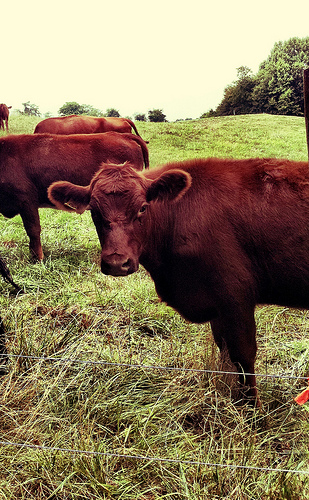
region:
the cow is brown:
[50, 169, 269, 375]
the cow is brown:
[4, 124, 177, 247]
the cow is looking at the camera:
[48, 139, 215, 332]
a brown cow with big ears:
[47, 152, 186, 296]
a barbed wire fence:
[82, 363, 282, 485]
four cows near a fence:
[1, 101, 258, 267]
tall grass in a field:
[24, 348, 173, 410]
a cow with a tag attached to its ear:
[50, 150, 183, 290]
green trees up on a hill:
[168, 43, 305, 132]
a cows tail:
[114, 133, 157, 170]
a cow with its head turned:
[69, 156, 188, 282]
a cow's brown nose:
[80, 239, 142, 293]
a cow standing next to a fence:
[37, 149, 281, 474]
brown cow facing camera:
[41, 153, 305, 425]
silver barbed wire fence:
[1, 337, 307, 498]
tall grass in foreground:
[4, 233, 305, 493]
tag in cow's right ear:
[63, 200, 80, 216]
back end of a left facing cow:
[95, 130, 161, 177]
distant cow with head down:
[25, 112, 143, 141]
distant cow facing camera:
[0, 100, 13, 132]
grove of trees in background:
[11, 32, 305, 118]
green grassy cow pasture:
[0, 100, 306, 498]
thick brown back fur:
[142, 151, 307, 179]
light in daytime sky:
[3, 0, 307, 115]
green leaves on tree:
[258, 38, 307, 112]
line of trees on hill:
[18, 36, 308, 159]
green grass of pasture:
[0, 117, 306, 327]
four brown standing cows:
[0, 102, 306, 382]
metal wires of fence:
[0, 352, 308, 475]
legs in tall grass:
[7, 325, 299, 493]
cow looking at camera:
[49, 161, 190, 275]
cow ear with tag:
[46, 181, 90, 214]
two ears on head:
[50, 161, 192, 277]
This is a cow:
[44, 156, 302, 411]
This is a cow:
[0, 128, 158, 297]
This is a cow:
[28, 103, 164, 165]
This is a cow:
[0, 94, 18, 128]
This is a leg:
[218, 291, 276, 453]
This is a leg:
[199, 301, 243, 420]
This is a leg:
[22, 193, 57, 280]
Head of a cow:
[43, 145, 201, 310]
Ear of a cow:
[143, 165, 201, 218]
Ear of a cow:
[43, 173, 89, 235]